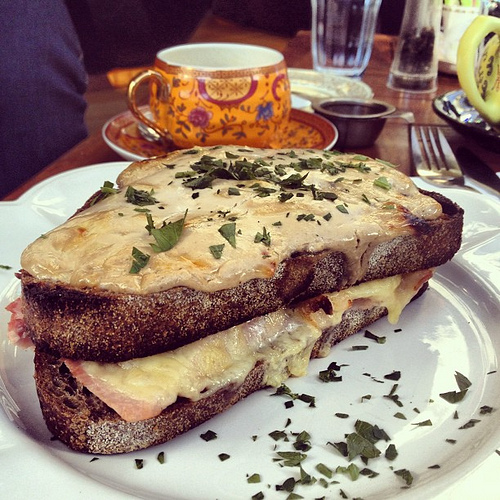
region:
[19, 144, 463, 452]
large sandwich on plate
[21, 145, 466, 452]
Large Sandwich with melted cheese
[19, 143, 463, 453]
Sandwich with green garnish on top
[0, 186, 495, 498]
large white plate with sandwich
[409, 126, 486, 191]
Top of silver fork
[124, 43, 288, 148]
beautiful, colorful teacup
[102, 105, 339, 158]
colorful, matching saucer for teacup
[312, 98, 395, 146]
small, brown container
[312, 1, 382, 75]
empty water glass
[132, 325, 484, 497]
green garnish on plate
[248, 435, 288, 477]
part of a plate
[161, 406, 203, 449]
edge of a plate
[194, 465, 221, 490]
part of a plate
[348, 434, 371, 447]
part of a leave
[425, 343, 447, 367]
edge of a shade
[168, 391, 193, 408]
edge of a cream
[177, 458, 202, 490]
part of a plate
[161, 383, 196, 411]
part of some cream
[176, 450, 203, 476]
part of a plate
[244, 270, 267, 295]
edge of a bread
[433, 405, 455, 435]
edge of a plate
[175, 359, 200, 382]
part of some cream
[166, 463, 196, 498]
part of a plate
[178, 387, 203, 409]
part of a bread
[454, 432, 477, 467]
edge of a plate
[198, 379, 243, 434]
part of a bread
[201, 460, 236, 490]
part of a plate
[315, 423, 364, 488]
the plate is white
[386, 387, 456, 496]
the plate is white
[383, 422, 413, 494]
the plate is white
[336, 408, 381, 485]
the plate is white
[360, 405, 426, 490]
the plate is white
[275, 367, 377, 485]
the plate is white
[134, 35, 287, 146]
an orange coffe cup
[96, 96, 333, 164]
an orange saucer dish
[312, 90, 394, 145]
a black condiment cup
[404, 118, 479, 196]
a silver fork utensil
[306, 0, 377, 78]
a clear drinking glass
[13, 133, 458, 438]
a browned sandwich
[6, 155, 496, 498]
a ceramic white plate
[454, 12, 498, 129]
a yellow coffee mug handle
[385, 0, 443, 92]
a clear pepper shaker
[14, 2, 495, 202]
a dark brown table